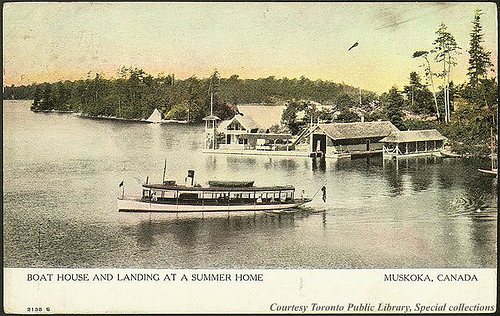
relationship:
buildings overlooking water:
[203, 113, 447, 160] [2, 90, 495, 265]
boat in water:
[116, 156, 310, 224] [392, 194, 463, 241]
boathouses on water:
[311, 117, 447, 164] [313, 153, 478, 208]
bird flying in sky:
[326, 34, 364, 62] [7, 3, 412, 75]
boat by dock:
[438, 146, 471, 158] [378, 128, 446, 166]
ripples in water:
[424, 187, 491, 222] [2, 90, 495, 265]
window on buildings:
[234, 119, 242, 132] [215, 105, 341, 152]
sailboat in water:
[144, 107, 163, 124] [2, 90, 495, 265]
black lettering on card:
[5, 267, 495, 314] [3, 2, 494, 310]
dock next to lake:
[368, 117, 457, 164] [326, 163, 493, 271]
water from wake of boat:
[329, 178, 485, 218] [116, 159, 312, 214]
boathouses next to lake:
[291, 120, 400, 159] [4, 100, 498, 268]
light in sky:
[287, 67, 388, 81] [4, 2, 496, 95]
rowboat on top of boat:
[205, 180, 253, 187] [116, 181, 311, 211]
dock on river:
[378, 128, 446, 166] [9, 110, 103, 252]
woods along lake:
[2, 62, 499, 157] [2, 99, 498, 268]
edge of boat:
[474, 167, 497, 175] [473, 160, 498, 187]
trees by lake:
[375, 10, 499, 146] [2, 99, 498, 268]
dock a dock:
[378, 128, 446, 166] [378, 128, 446, 166]